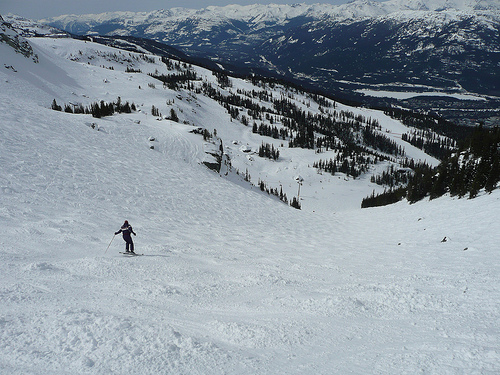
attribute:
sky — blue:
[0, 0, 370, 24]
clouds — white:
[26, 16, 81, 34]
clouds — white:
[23, 4, 70, 15]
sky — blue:
[128, 1, 159, 8]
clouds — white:
[118, 2, 128, 8]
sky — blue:
[2, 1, 349, 15]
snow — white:
[330, 5, 476, 25]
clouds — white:
[21, 7, 63, 9]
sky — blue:
[2, 2, 173, 13]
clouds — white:
[400, 0, 486, 14]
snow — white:
[4, 11, 496, 373]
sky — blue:
[23, 0, 231, 22]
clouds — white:
[28, 3, 188, 20]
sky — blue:
[22, 3, 234, 16]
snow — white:
[188, 215, 317, 306]